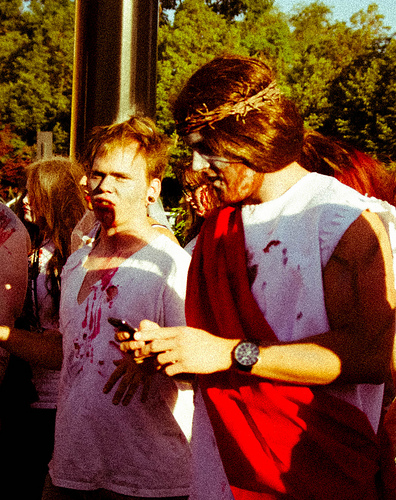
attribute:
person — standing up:
[3, 157, 86, 494]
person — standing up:
[172, 145, 236, 250]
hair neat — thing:
[70, 63, 277, 195]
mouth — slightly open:
[93, 196, 119, 210]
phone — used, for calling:
[107, 314, 134, 329]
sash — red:
[190, 207, 393, 498]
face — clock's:
[235, 344, 255, 362]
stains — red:
[81, 298, 102, 334]